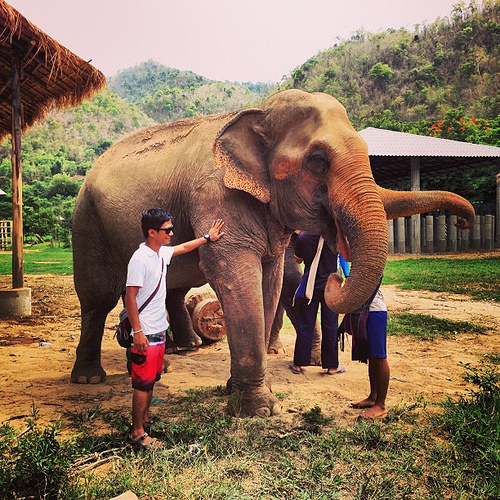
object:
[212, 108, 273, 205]
ear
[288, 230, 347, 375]
person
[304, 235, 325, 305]
stripe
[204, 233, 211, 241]
watch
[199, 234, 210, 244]
wrist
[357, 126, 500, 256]
hut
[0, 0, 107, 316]
hut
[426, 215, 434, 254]
support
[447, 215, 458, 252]
support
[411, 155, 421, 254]
support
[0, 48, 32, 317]
support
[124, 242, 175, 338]
shirt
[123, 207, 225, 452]
man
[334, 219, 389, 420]
man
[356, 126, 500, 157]
roof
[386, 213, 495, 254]
pole fencing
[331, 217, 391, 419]
person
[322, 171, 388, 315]
trunk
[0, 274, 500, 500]
dirt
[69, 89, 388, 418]
elephant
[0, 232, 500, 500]
grass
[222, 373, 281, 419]
foot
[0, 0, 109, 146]
roof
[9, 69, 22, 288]
pole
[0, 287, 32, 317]
cement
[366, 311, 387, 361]
shorts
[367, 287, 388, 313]
shirt